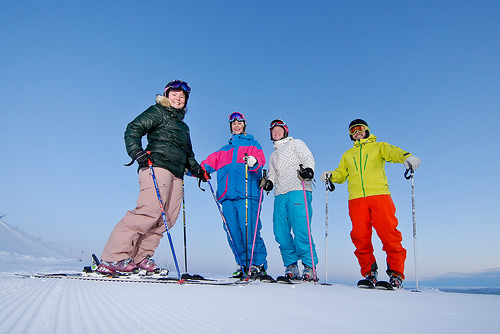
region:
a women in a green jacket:
[83, 55, 210, 282]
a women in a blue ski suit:
[199, 107, 277, 299]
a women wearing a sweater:
[250, 109, 327, 291]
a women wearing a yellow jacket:
[307, 112, 435, 296]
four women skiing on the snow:
[57, 71, 446, 303]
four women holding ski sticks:
[8, 88, 438, 313]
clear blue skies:
[14, 9, 192, 92]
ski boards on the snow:
[36, 250, 428, 332]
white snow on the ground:
[17, 280, 234, 331]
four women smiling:
[111, 43, 448, 309]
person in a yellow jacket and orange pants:
[321, 113, 426, 289]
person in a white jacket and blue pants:
[262, 115, 320, 281]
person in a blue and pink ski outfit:
[198, 107, 273, 277]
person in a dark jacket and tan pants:
[103, 76, 202, 280]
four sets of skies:
[18, 266, 432, 291]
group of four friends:
[89, 73, 421, 294]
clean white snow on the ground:
[13, 277, 476, 332]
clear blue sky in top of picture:
[1, 2, 498, 123]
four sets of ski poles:
[138, 148, 425, 294]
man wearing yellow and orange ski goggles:
[347, 117, 372, 136]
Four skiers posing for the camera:
[88, 72, 423, 292]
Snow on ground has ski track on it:
[11, 277, 365, 332]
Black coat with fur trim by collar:
[121, 88, 206, 168]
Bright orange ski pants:
[343, 197, 404, 274]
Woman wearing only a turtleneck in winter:
[259, 111, 316, 196]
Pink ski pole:
[300, 176, 323, 281]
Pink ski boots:
[83, 252, 165, 275]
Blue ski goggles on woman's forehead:
[222, 107, 247, 124]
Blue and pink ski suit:
[211, 130, 271, 270]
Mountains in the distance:
[436, 265, 499, 287]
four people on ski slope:
[39, 62, 484, 332]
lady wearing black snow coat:
[112, 65, 204, 177]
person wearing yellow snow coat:
[319, 113, 411, 200]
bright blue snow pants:
[272, 180, 334, 293]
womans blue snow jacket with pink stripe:
[201, 126, 268, 202]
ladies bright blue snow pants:
[210, 191, 275, 281]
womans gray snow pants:
[97, 157, 175, 284]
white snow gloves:
[397, 141, 429, 185]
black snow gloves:
[293, 160, 317, 190]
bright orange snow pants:
[339, 191, 428, 298]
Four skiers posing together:
[106, 74, 427, 291]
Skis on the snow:
[37, 251, 225, 296]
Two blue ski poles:
[139, 144, 224, 282]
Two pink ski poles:
[245, 175, 322, 285]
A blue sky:
[136, 9, 418, 85]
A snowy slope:
[3, 192, 106, 271]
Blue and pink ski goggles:
[228, 108, 245, 125]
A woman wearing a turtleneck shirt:
[259, 135, 317, 199]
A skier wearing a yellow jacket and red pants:
[328, 119, 417, 273]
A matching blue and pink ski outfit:
[205, 131, 270, 270]